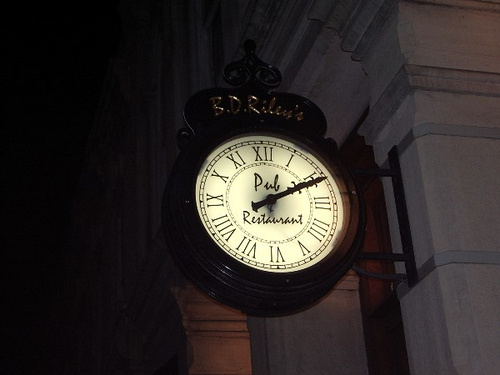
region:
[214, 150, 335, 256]
white face of the clock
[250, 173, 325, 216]
black hands of the clock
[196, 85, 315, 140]
gold lettering on the top of the clock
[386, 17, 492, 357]
grey concrete corner of a building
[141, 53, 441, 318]
a black analog clock attached to a building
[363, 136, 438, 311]
the black mounting plate of the clock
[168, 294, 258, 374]
light shining on the alcove of the building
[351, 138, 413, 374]
wooden door to the pub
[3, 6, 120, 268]
black night sky over the building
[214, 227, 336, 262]
roman numerals on the face of the clock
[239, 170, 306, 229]
pub restaurant saying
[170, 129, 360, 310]
wooden clock with roman numerals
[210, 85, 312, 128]
word on top of the clock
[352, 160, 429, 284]
bars to hold the clock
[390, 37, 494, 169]
gray stone pillar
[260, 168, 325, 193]
hand of the clock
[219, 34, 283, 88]
decoration on top of the clock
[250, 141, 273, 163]
roman numeral 12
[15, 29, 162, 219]
part of the gray building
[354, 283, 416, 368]
brown window on building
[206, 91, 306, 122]
name of a restaurant/pub B.D. Riley's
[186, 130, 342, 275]
bd riley's clock that says it's 2:11 am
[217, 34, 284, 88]
nice little embellishment on top of the clock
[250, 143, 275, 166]
roman numeral for 12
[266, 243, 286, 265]
roman numeral 6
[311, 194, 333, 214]
three capital letter I's making the roman numeral 3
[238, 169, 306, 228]
pub and restaurant written in black script that is on the white clock face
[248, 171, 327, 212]
nicely designed minute and hour hands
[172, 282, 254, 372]
light shining on the building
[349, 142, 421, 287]
black cast iron anchor for the clock to stay on the wall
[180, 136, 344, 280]
The clock is white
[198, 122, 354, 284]
The clock is lit up.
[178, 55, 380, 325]
The frame is black.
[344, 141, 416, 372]
The clock is attached to the building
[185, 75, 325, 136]
The lettering is gold.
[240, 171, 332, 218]
The hands are black.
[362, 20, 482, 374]
The building is brick.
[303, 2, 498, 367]
The pillar is thick.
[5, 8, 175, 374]
It is night outside.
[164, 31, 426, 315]
The clock is decorative.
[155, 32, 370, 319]
A clock attacked to the side of a building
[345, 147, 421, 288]
Metal structure affixing clock to the building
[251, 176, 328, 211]
Clock hands overlapping at around 2:10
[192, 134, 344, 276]
An analog clock face with roman numerals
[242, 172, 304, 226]
Text on the clock face saying "Pub Restaurant"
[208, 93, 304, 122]
Engraved text on clock saying "B. D. Riley's"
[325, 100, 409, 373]
A dark door set in the building wall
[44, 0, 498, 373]
A gray stone old-fashioned building exterior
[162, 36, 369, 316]
A metal analog clock with many decorative elements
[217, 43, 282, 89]
A decoration on top of the clock